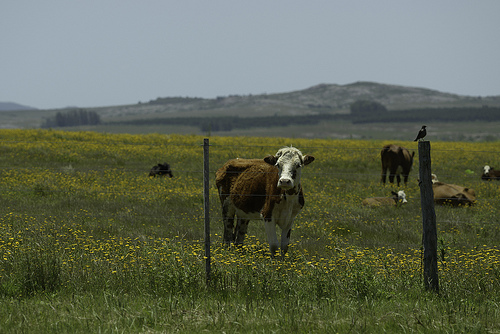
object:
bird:
[412, 124, 428, 141]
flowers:
[271, 252, 277, 253]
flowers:
[173, 251, 179, 258]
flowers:
[173, 234, 183, 237]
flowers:
[111, 270, 113, 274]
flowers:
[386, 253, 393, 258]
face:
[481, 163, 491, 176]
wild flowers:
[12, 251, 71, 286]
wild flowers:
[3, 151, 163, 203]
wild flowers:
[217, 136, 255, 160]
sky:
[405, 2, 498, 64]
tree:
[92, 111, 101, 124]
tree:
[87, 109, 94, 124]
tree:
[82, 109, 89, 125]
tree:
[55, 110, 62, 125]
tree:
[65, 115, 72, 126]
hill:
[314, 73, 426, 113]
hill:
[202, 90, 319, 129]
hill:
[102, 92, 212, 123]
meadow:
[79, 104, 113, 129]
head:
[261, 148, 316, 189]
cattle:
[213, 148, 314, 257]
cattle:
[417, 180, 477, 210]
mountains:
[101, 73, 471, 163]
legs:
[233, 215, 249, 244]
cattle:
[380, 141, 416, 186]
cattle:
[361, 187, 408, 209]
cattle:
[479, 160, 500, 180]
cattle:
[149, 161, 173, 178]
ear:
[263, 154, 277, 166]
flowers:
[133, 236, 188, 268]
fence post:
[414, 142, 440, 293]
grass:
[26, 276, 64, 321]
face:
[277, 147, 297, 192]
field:
[2, 130, 498, 332]